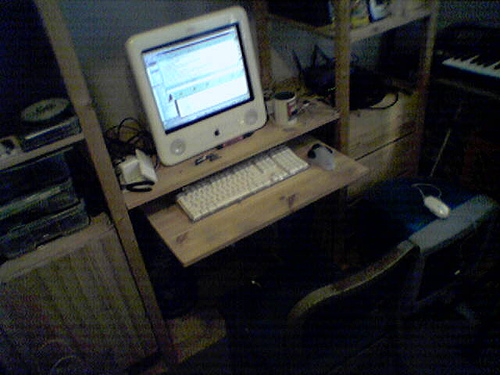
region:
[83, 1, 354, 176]
an apple computer monitor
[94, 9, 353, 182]
an old apple computer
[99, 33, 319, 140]
an old computer turned on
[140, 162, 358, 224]
an old apple keyboard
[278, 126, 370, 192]
a mouse with a ball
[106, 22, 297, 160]
a computer monitor with speakers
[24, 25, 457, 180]
a wooden desk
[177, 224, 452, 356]
a metal chair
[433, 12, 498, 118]
a keyboard on a stand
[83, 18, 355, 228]
an apple computer with keyboard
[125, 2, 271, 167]
computer monitor is white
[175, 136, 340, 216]
computer keyboard and mouse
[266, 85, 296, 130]
large coffee mug on right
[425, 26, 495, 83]
electronic keyboard is black and white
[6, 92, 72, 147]
compact discs on the shelf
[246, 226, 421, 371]
desk chair for computer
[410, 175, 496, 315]
mouse and monitor on the floor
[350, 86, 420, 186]
desk drawers are wooden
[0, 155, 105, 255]
plastic storage cases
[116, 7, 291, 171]
large flat screen monitor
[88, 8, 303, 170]
a computer monitor on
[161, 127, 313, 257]
a white computer keyboard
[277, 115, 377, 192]
a computer mouse with a ball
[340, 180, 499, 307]
a blue monitor on the ground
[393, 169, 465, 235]
a white mouse on top of a blue monitor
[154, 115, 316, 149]
speakers on the computer monitor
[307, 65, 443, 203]
wooden drawers on the desk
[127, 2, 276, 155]
the computer monitor on the desk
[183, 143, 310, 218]
the keyboard on the shelf below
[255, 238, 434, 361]
the chair next to the desk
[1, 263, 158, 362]
a cabinet next to the desk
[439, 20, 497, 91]
a keyboard off to the side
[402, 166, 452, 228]
the mouse off to the side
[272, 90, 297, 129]
a cup next to the monitor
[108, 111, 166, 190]
wires behind the monitor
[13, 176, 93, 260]
boxes on the shelf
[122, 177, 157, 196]
the pliers on the shelf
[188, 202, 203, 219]
a key on a keyboard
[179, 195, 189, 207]
a key on a keyboard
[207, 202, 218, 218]
a key on a keyboard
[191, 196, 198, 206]
a key on a keyboard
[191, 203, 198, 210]
a key on a keyboard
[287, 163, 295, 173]
a key on a keyboard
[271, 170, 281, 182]
a key on a keyboard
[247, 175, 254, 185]
a key on a keyboard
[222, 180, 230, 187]
a key on a keyboard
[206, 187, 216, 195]
a key on a keyboard